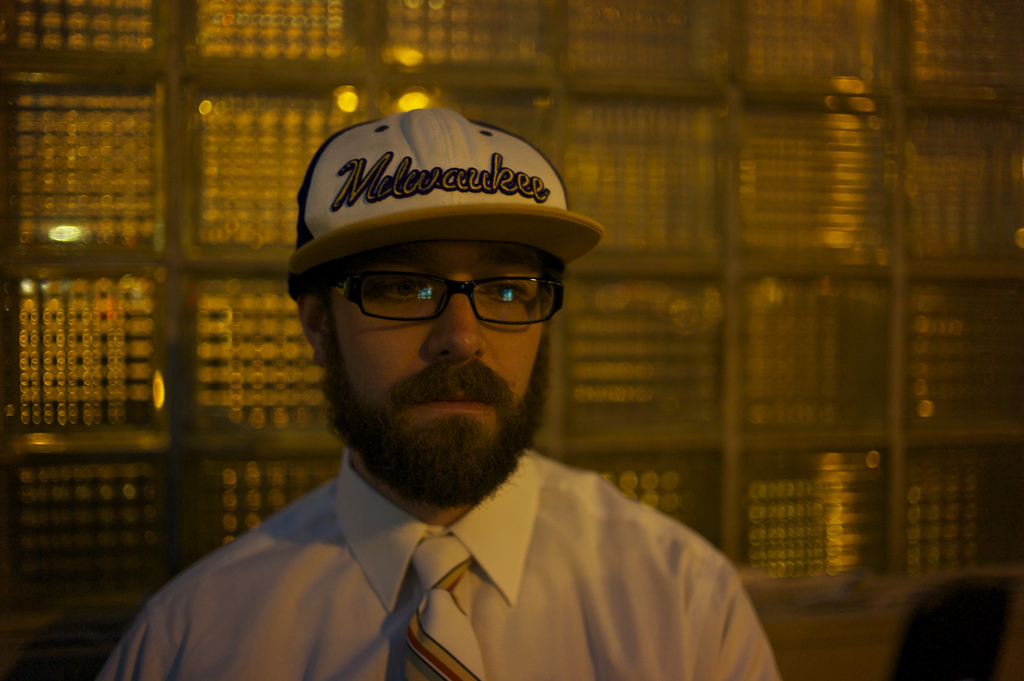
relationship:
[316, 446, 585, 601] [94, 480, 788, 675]
collar on dress shirt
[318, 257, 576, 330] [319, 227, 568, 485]
glasses on face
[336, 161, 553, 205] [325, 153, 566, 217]
letters on cap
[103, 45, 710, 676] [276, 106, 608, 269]
man wearing cap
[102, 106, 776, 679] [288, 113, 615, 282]
man wearing cap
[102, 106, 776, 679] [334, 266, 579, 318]
man wearing glasses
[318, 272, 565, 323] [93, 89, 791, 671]
glasses behind man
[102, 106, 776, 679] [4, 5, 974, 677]
man in front of wall